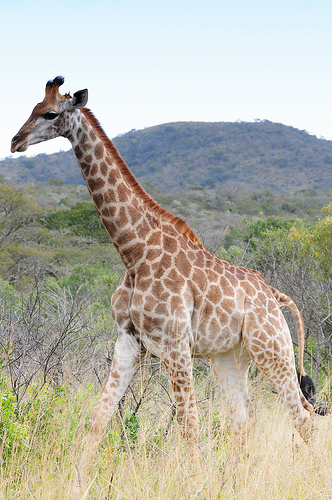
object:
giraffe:
[10, 73, 331, 500]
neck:
[70, 138, 195, 264]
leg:
[75, 327, 155, 499]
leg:
[164, 337, 205, 499]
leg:
[214, 351, 261, 498]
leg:
[241, 323, 331, 496]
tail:
[271, 284, 318, 402]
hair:
[295, 372, 317, 406]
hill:
[133, 117, 331, 196]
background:
[0, 0, 330, 266]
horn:
[45, 79, 53, 96]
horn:
[52, 76, 64, 92]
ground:
[7, 207, 331, 497]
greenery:
[2, 310, 73, 499]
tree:
[207, 178, 252, 213]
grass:
[13, 386, 330, 499]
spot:
[163, 267, 190, 295]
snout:
[10, 130, 25, 143]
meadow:
[0, 286, 330, 500]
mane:
[81, 104, 205, 250]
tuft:
[298, 373, 317, 405]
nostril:
[12, 137, 18, 141]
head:
[8, 76, 88, 153]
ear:
[73, 88, 89, 109]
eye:
[41, 110, 60, 121]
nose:
[10, 135, 20, 145]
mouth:
[11, 140, 27, 154]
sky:
[156, 1, 331, 111]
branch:
[41, 279, 96, 387]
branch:
[121, 391, 157, 497]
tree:
[186, 183, 204, 206]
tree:
[254, 188, 278, 217]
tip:
[295, 369, 314, 405]